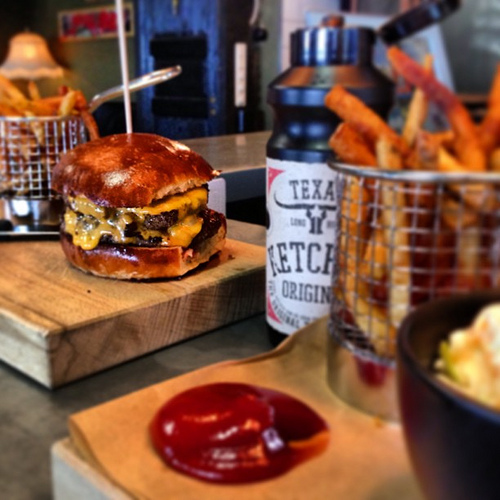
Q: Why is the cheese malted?
A: Hot.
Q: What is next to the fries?
A: Ketchup.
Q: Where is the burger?
A: On the cutting board.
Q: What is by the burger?
A: Ketchup bottle.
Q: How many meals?
A: One.